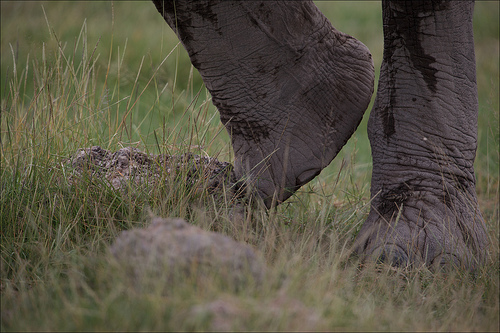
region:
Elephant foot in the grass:
[330, 53, 499, 320]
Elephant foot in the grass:
[357, 23, 493, 288]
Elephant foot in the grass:
[360, 52, 495, 289]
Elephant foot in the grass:
[356, 47, 498, 264]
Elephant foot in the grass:
[353, 54, 499, 282]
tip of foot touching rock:
[65, 135, 287, 242]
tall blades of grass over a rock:
[57, 22, 176, 219]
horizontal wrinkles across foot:
[371, 100, 476, 195]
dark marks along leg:
[381, 7, 443, 143]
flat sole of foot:
[257, 47, 379, 214]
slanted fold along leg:
[389, 37, 471, 174]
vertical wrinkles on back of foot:
[295, 30, 371, 132]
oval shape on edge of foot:
[286, 165, 323, 189]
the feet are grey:
[152, 8, 499, 299]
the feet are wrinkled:
[160, 13, 491, 298]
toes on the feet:
[366, 223, 467, 280]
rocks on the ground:
[49, 108, 299, 308]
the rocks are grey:
[71, 117, 285, 320]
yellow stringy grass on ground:
[5, 10, 247, 311]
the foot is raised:
[150, 9, 394, 205]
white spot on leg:
[411, 123, 442, 158]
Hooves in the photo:
[180, 30, 483, 280]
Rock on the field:
[98, 136, 230, 287]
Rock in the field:
[105, 205, 255, 295]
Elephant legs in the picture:
[210, 22, 497, 237]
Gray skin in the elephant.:
[389, 112, 457, 222]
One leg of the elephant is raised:
[152, 0, 376, 212]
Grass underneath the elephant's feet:
[1, 0, 499, 332]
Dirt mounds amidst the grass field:
[61, 144, 327, 331]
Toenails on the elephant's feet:
[248, 165, 460, 273]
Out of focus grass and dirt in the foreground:
[0, 214, 499, 331]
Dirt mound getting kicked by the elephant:
[63, 146, 253, 228]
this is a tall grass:
[327, 156, 355, 281]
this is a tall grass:
[11, 218, 41, 328]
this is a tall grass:
[63, 140, 80, 257]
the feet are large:
[220, 23, 322, 128]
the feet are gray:
[199, 9, 376, 166]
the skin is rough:
[189, 33, 350, 154]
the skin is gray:
[229, 53, 333, 139]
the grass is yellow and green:
[26, 73, 150, 226]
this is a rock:
[103, 201, 216, 263]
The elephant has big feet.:
[170, 50, 493, 296]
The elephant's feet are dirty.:
[149, 5, 481, 281]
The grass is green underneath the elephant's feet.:
[13, 36, 498, 331]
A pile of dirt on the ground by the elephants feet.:
[57, 143, 250, 295]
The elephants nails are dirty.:
[342, 240, 467, 277]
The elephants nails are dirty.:
[244, 157, 318, 211]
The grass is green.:
[29, 207, 499, 332]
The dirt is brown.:
[44, 150, 250, 292]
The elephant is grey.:
[141, 7, 499, 279]